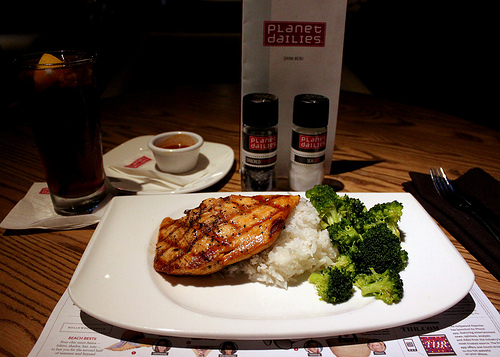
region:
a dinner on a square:
[64, 188, 460, 334]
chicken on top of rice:
[158, 182, 302, 289]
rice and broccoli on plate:
[300, 185, 402, 307]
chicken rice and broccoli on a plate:
[156, 188, 422, 306]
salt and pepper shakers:
[238, 90, 340, 185]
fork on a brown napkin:
[427, 171, 498, 257]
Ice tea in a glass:
[26, 36, 106, 231]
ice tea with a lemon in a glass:
[22, 41, 112, 218]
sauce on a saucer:
[126, 118, 224, 192]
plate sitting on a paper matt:
[63, 200, 489, 350]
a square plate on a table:
[68, 176, 450, 338]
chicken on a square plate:
[153, 175, 288, 273]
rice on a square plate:
[255, 210, 336, 295]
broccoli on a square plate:
[310, 183, 400, 303]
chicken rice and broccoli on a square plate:
[145, 191, 406, 302]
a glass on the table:
[36, 20, 104, 228]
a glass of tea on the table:
[26, 40, 96, 215]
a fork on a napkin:
[425, 160, 496, 270]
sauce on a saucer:
[132, 119, 214, 191]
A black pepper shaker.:
[243, 93, 283, 190]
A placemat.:
[23, 201, 498, 354]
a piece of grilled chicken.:
[160, 195, 299, 277]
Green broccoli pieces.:
[309, 182, 411, 303]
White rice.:
[219, 195, 338, 289]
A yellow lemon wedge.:
[35, 51, 61, 90]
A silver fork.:
[427, 156, 497, 248]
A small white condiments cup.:
[144, 132, 204, 172]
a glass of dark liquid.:
[14, 49, 116, 214]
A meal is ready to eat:
[28, 41, 479, 347]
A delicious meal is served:
[23, 32, 469, 353]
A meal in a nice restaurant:
[40, 47, 478, 317]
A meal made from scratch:
[11, 60, 496, 331]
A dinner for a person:
[12, 38, 497, 340]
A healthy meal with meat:
[3, 86, 498, 341]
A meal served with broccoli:
[31, 85, 453, 320]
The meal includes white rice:
[10, 92, 488, 352]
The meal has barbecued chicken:
[5, 102, 490, 333]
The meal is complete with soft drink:
[9, 30, 486, 327]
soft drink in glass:
[30, 53, 113, 217]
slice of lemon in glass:
[38, 52, 63, 83]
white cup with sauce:
[152, 130, 203, 173]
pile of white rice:
[220, 198, 334, 285]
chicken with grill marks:
[154, 192, 298, 274]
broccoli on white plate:
[308, 183, 403, 303]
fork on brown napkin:
[402, 167, 498, 277]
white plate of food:
[67, 190, 472, 340]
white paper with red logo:
[240, 1, 347, 178]